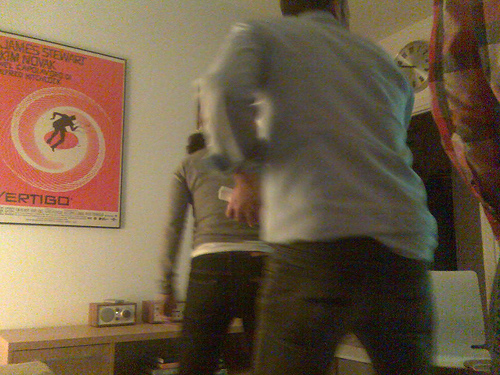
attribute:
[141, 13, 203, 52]
wall — white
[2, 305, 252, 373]
desk — wooden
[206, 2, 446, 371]
man — blur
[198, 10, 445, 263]
shirt — plaid 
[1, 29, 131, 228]
sign — red, black, white, wall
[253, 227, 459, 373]
pants — jeans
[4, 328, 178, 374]
stand — brown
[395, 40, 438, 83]
clock — silver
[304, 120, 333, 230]
shirt — grey